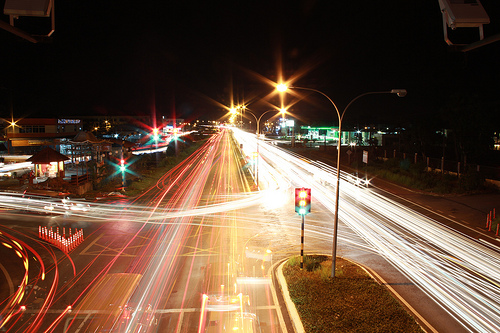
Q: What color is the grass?
A: Green.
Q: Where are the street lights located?
A: In the median.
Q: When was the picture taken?
A: At night.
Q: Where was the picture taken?
A: On the street.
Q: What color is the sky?
A: Black.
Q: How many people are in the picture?
A: None.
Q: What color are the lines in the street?
A: White, red, blue and yellow.